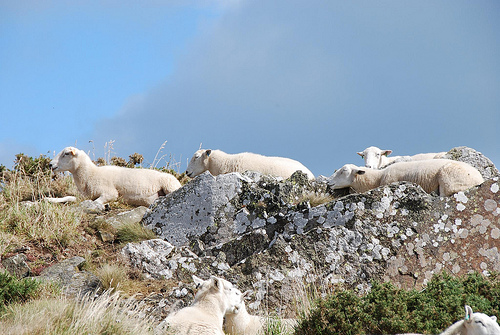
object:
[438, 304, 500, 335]
sheep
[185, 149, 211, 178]
head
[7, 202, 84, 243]
grass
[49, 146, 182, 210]
sheep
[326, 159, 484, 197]
sheep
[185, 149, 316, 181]
sheep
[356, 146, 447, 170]
sheep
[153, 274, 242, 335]
sheep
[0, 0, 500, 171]
sky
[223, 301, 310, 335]
sheep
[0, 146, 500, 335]
hill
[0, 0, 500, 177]
cloud